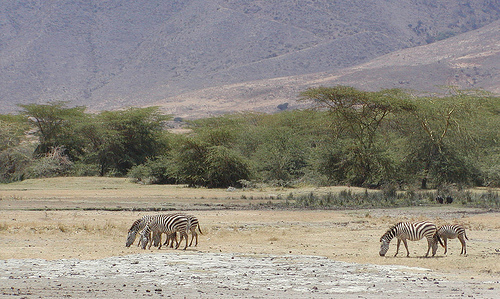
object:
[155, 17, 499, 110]
hill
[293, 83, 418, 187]
tree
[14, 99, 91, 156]
tree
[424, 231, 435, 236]
stripes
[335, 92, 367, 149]
branches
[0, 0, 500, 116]
mountains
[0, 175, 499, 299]
barren land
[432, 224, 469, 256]
zebra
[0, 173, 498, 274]
grass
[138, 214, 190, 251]
zebra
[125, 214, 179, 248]
zebra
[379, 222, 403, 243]
mane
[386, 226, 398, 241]
neck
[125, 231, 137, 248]
head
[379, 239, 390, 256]
head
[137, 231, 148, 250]
head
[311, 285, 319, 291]
pebbles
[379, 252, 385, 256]
muzzle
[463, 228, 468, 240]
zebra tail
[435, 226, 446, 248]
zebra tail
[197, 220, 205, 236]
zebra tail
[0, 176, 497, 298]
plain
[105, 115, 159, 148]
thorns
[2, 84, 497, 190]
foliage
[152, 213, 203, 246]
zebra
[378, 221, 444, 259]
zebra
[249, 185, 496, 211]
vegetation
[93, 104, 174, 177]
tree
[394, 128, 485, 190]
tree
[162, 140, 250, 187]
tree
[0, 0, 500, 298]
photo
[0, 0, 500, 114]
background